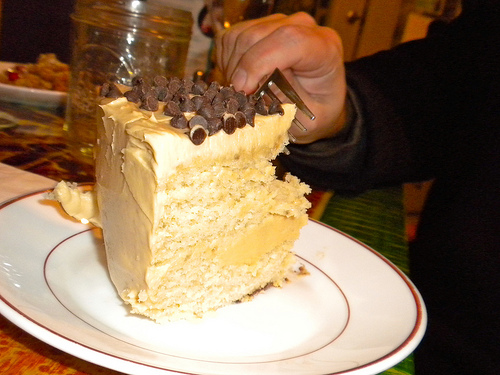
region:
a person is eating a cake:
[6, 6, 494, 370]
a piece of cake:
[42, 15, 356, 317]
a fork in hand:
[175, 9, 426, 176]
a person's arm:
[190, 3, 491, 168]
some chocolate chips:
[109, 49, 301, 167]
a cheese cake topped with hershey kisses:
[95, 53, 313, 325]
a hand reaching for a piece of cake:
[166, 8, 386, 179]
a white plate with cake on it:
[0, 167, 430, 374]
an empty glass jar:
[62, 1, 193, 173]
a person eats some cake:
[86, 14, 461, 339]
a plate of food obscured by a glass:
[5, 48, 102, 128]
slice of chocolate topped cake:
[89, 74, 317, 314]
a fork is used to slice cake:
[186, 11, 366, 179]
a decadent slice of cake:
[0, 71, 422, 368]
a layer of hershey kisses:
[119, 70, 290, 167]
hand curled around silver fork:
[212, 16, 348, 143]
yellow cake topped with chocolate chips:
[90, 65, 310, 320]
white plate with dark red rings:
[2, 155, 427, 366]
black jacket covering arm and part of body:
[280, 5, 490, 365]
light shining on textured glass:
[60, 1, 195, 176]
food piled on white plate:
[0, 45, 65, 106]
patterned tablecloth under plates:
[5, 96, 410, 366]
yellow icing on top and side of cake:
[95, 77, 305, 302]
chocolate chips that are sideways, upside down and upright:
[121, 65, 281, 141]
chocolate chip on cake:
[187, 125, 207, 144]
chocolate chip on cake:
[188, 115, 207, 130]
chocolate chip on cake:
[205, 115, 220, 132]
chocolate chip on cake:
[221, 111, 236, 131]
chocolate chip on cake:
[236, 110, 247, 130]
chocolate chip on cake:
[239, 107, 257, 127]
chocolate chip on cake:
[168, 109, 187, 128]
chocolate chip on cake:
[136, 96, 163, 113]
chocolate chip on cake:
[176, 91, 193, 111]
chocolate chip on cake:
[122, 85, 139, 101]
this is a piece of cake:
[74, 74, 294, 305]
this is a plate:
[0, 185, 427, 374]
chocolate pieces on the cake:
[129, 72, 153, 91]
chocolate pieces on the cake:
[179, 102, 205, 149]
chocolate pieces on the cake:
[209, 85, 230, 110]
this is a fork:
[217, 29, 320, 129]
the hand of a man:
[218, 8, 373, 154]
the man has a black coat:
[340, 43, 499, 358]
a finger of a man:
[223, 28, 340, 96]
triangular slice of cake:
[96, 72, 308, 317]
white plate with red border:
[1, 178, 427, 372]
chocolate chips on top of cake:
[100, 66, 283, 144]